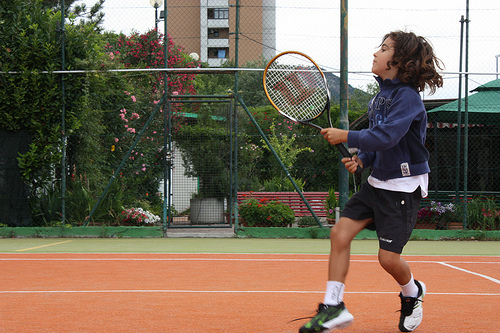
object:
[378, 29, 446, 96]
hair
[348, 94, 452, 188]
sweater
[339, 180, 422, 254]
shorts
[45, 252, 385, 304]
line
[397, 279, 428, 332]
shoe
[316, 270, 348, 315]
sock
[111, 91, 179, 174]
flower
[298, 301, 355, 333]
shoes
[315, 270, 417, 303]
socks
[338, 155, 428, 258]
shorts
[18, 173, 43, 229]
bushes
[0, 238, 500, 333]
court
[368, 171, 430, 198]
shirt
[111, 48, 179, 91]
flower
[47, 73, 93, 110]
bushes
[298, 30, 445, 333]
child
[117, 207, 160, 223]
flower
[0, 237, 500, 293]
ground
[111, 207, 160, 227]
flower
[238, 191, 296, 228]
flowers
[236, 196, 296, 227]
bush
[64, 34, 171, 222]
tree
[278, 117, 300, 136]
flowers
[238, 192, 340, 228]
bench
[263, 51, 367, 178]
racket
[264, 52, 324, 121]
strings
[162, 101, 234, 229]
door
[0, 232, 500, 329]
tennis court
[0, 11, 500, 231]
fence